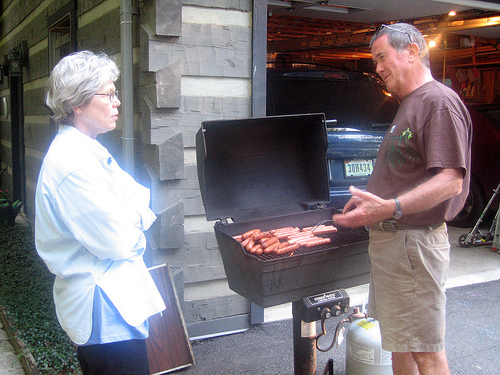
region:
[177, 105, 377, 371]
hotdogs on barbecue grill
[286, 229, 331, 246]
row of uncooked hotdogs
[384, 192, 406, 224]
watch on wrist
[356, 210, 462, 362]
tan shorts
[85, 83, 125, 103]
eyes glasses on woman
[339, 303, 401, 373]
propane tank next to grill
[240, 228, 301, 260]
row of cooked hot dogs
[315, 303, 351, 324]
knobs on front of grill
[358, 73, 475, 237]
dark lavender short sleeve t-shirt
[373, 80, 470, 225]
the man is wearing a t shirt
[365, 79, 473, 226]
the t shirt is brown in color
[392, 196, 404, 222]
the man is wearing a watch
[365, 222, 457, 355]
the man is wearing shorts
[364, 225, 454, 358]
the shorts are khaki in color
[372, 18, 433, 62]
the man has grey hair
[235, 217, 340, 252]
the man is broiling hot dogs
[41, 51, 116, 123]
the woman has grey hair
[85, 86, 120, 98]
woman is wearing glasses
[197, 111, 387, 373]
a barbecue is on a pole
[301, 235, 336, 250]
this is a hotdog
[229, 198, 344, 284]
these are the hotdogs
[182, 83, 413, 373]
this is a grill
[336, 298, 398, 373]
this is a tank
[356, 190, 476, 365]
these are khaki shorts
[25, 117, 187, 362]
this is a jacket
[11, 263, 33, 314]
this is the grass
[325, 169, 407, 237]
this is a hand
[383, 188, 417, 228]
this is a watch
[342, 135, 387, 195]
this is a license plate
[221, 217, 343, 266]
meat cooking on a bbq.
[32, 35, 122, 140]
a woman wearing glasses.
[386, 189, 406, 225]
a watch on a man's wrist.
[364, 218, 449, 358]
A man wearing pair of shorts.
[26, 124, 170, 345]
A woman wearing a white shirt.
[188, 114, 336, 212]
a black metal grill lid.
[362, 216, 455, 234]
a belt around a man's waist.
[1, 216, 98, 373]
a green area near a building.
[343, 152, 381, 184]
a license plate.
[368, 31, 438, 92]
a man with gray hair.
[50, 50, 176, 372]
a lady in a white shirt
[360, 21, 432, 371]
a man in a brown shirt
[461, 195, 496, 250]
a scooter in the garage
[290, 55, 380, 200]
a van in the garage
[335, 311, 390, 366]
a propane tank on the grill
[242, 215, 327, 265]
hot dogs on the grill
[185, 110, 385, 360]
a black grill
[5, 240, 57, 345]
plants on the ground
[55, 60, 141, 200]
a lady with glasses on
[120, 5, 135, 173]
the rain gutter